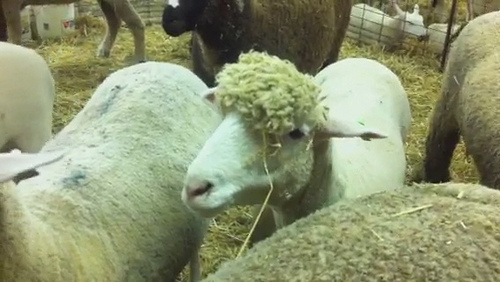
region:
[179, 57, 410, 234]
a white wooly sheep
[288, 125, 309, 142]
a sheep's left eye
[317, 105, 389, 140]
a sheep's left ear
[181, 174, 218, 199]
a sheep's pink nose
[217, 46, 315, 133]
a sheep's haircut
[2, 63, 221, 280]
a sheep's rear end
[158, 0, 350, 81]
a black and brown sheep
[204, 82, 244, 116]
a sheep's right ear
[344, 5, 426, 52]
a sheep laying in the grass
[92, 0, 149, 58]
a sheep's rear legs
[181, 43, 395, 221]
the head of a sheep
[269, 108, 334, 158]
the eye of a sheep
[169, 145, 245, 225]
the nose of a sheep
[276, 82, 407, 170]
the ear of a sheep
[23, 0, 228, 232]
the back of a sheep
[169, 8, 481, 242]
sheeps in a sheep pen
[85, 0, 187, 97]
the legs of a sheep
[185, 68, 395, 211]
a white sheep head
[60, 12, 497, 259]
sheeps side by side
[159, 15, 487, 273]
sheeps standing on hay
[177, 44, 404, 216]
sheared white sheep with blonde hair on top of head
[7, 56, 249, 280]
unsheared white sheep with dirt on it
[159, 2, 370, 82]
unsheared brown unidentifiable animal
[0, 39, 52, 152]
rear portion of unidentifiable animal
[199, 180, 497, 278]
unsheared brown sheep with hay in fur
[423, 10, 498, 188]
unsheared brown animal with dirty underbelly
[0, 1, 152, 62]
bottom of legs of unidentifiable animal with hooves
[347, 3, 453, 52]
metal fence encaging animals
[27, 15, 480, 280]
hay and straw lining ground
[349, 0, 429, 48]
sheared white sheep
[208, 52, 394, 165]
sheep has a puff of hair on head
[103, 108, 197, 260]
sheep has been sheared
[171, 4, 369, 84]
sheep is black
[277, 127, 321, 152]
sheep has black eyes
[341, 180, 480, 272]
sheep has dirt on back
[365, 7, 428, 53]
sheep is laying in the hay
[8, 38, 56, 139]
behind of a sheep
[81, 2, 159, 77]
legs of a sheep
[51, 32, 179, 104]
hay on the ground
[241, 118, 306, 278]
hay on the sheeps face